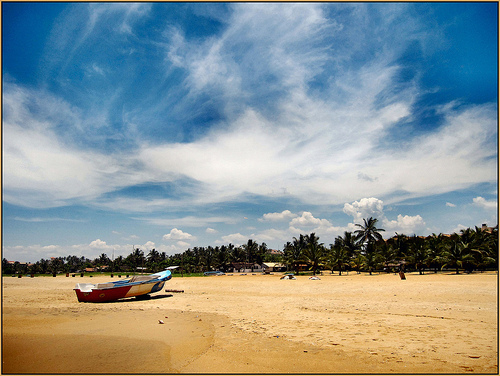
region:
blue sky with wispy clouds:
[8, 10, 490, 222]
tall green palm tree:
[344, 211, 384, 264]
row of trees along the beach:
[21, 228, 486, 274]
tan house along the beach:
[217, 247, 313, 277]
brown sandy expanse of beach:
[15, 273, 490, 356]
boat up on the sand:
[64, 268, 179, 308]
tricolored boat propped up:
[72, 265, 181, 306]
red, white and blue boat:
[80, 264, 172, 302]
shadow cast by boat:
[126, 288, 175, 303]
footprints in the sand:
[258, 294, 485, 365]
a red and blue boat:
[65, 247, 187, 313]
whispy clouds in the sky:
[87, 85, 392, 185]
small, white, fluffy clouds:
[342, 193, 429, 233]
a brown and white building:
[208, 248, 283, 285]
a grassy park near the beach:
[22, 260, 139, 283]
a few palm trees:
[281, 210, 485, 272]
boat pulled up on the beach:
[75, 254, 195, 319]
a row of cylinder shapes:
[14, 266, 124, 281]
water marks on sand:
[28, 302, 228, 367]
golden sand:
[204, 271, 435, 351]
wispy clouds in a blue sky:
[4, 10, 489, 192]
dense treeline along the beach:
[7, 221, 488, 273]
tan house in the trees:
[223, 253, 300, 274]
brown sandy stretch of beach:
[8, 274, 476, 356]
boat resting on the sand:
[63, 269, 188, 309]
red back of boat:
[68, 266, 195, 303]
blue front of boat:
[139, 266, 178, 308]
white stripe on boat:
[97, 268, 162, 313]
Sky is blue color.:
[41, 33, 133, 85]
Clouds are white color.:
[20, 134, 437, 221]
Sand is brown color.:
[239, 286, 394, 328]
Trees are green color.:
[172, 233, 478, 271]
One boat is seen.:
[65, 268, 180, 310]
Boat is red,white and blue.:
[66, 268, 211, 326]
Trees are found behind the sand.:
[38, 248, 476, 273]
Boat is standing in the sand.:
[58, 273, 204, 314]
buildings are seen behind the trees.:
[161, 256, 317, 274]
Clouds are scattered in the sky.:
[22, 56, 462, 213]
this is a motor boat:
[65, 268, 174, 313]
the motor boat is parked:
[75, 263, 173, 308]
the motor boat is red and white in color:
[67, 265, 170, 309]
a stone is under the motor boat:
[133, 292, 153, 300]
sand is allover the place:
[210, 301, 496, 373]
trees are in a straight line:
[198, 226, 480, 273]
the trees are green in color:
[178, 227, 491, 264]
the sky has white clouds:
[20, 0, 492, 206]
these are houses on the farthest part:
[237, 261, 301, 272]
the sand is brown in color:
[217, 306, 492, 375]